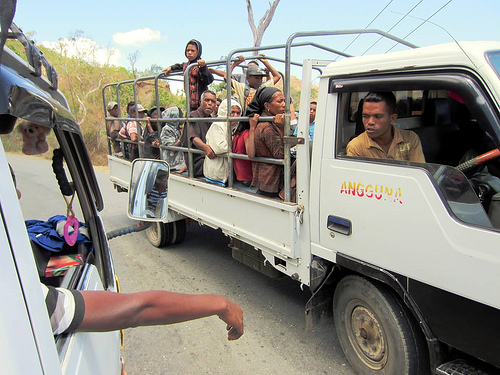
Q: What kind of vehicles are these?
A: Trucks.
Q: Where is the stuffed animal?
A: On the windshield of the man on the left.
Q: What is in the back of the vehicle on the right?
A: People.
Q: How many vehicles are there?
A: Two.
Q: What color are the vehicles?
A: White.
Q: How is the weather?
A: Sunny.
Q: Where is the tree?
A: Behind the truck on the right.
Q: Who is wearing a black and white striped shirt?
A: The person in the front seat of the truck on the left.